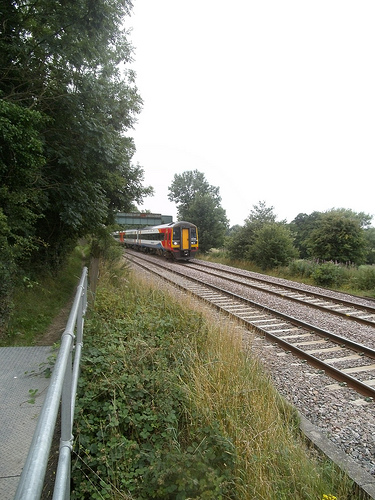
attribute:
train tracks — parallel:
[240, 265, 335, 339]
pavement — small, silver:
[0, 346, 60, 498]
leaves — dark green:
[44, 88, 147, 254]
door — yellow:
[181, 228, 188, 249]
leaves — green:
[24, 338, 61, 400]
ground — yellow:
[310, 108, 335, 156]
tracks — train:
[281, 280, 369, 312]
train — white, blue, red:
[120, 218, 210, 256]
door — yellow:
[178, 223, 193, 254]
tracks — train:
[128, 248, 373, 441]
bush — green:
[287, 254, 320, 278]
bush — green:
[310, 257, 349, 287]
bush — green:
[348, 263, 373, 292]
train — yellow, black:
[116, 217, 207, 267]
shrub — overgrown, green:
[64, 373, 237, 498]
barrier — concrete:
[304, 424, 369, 486]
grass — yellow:
[152, 332, 251, 407]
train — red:
[155, 225, 176, 251]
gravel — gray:
[276, 363, 317, 394]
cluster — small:
[323, 492, 340, 498]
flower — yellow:
[322, 492, 327, 496]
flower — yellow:
[331, 493, 336, 497]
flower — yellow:
[327, 492, 331, 495]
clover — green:
[106, 368, 147, 409]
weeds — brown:
[186, 337, 293, 497]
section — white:
[121, 222, 159, 243]